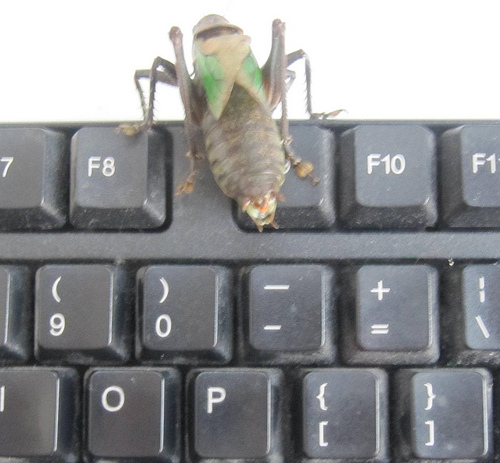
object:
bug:
[126, 10, 338, 228]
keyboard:
[5, 117, 499, 448]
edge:
[5, 114, 499, 136]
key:
[131, 263, 232, 358]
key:
[26, 261, 133, 359]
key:
[346, 259, 442, 357]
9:
[28, 262, 128, 362]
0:
[129, 263, 229, 359]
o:
[80, 363, 187, 449]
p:
[193, 363, 283, 454]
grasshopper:
[119, 1, 345, 243]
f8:
[71, 122, 169, 223]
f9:
[235, 122, 341, 232]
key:
[302, 367, 389, 454]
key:
[403, 363, 499, 452]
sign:
[346, 265, 438, 359]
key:
[0, 362, 79, 459]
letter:
[0, 384, 11, 416]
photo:
[3, 1, 495, 458]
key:
[235, 263, 335, 365]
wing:
[235, 42, 272, 112]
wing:
[196, 32, 249, 117]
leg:
[167, 22, 194, 195]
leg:
[126, 55, 177, 139]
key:
[442, 126, 500, 235]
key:
[1, 122, 71, 224]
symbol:
[453, 263, 499, 353]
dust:
[5, 230, 498, 262]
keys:
[0, 120, 500, 366]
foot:
[293, 157, 318, 190]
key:
[182, 367, 289, 451]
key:
[76, 362, 185, 458]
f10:
[337, 123, 442, 229]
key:
[62, 124, 174, 234]